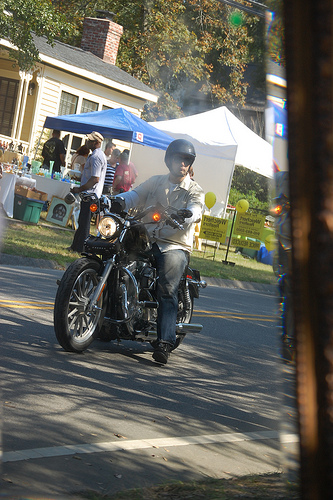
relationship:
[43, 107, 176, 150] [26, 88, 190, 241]
blue canopy to a tent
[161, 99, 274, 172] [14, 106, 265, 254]
canopy in yard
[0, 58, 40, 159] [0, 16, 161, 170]
porch on house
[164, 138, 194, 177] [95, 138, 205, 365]
helmet on man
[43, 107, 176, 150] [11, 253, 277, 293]
blue canopy on road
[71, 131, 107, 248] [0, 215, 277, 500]
man on ground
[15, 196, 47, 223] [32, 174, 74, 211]
bucket under table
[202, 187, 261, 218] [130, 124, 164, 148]
balloon on sign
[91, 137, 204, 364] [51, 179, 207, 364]
man riding motorcycle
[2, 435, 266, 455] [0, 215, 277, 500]
line in ground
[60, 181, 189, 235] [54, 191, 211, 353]
handlebars on motorcycle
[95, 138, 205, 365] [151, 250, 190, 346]
man wearing jeans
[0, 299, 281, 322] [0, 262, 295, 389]
line in street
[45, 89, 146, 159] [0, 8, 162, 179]
windows are on home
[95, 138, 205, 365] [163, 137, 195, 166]
man wearing helmet